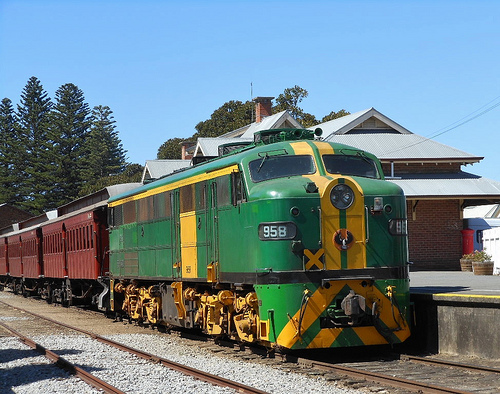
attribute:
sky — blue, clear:
[159, 1, 335, 72]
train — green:
[242, 147, 408, 354]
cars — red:
[40, 212, 104, 277]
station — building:
[409, 145, 463, 273]